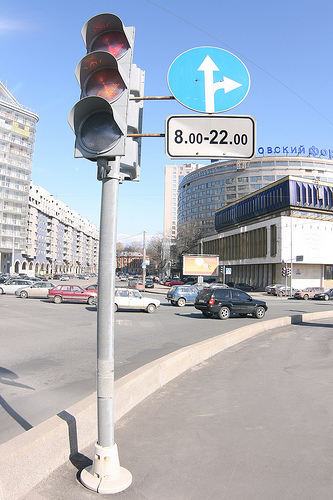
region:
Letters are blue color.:
[258, 142, 332, 158]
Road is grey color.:
[195, 405, 300, 466]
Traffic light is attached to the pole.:
[76, 16, 138, 186]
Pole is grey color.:
[100, 306, 119, 425]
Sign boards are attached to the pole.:
[163, 50, 257, 161]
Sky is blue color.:
[221, 14, 320, 46]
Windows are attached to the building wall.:
[3, 181, 68, 253]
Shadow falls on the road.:
[2, 367, 88, 469]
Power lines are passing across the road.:
[165, 8, 237, 49]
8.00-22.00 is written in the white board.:
[171, 119, 253, 158]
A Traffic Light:
[61, 9, 146, 166]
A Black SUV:
[190, 282, 269, 318]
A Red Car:
[43, 279, 95, 305]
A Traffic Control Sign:
[162, 41, 253, 112]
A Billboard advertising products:
[174, 246, 220, 278]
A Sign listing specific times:
[161, 112, 254, 156]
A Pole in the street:
[78, 179, 135, 484]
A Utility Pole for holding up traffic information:
[136, 226, 151, 285]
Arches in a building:
[11, 257, 91, 275]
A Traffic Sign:
[292, 252, 310, 267]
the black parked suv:
[193, 287, 261, 333]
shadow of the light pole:
[4, 362, 87, 467]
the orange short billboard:
[183, 249, 224, 288]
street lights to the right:
[278, 259, 297, 283]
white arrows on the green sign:
[183, 50, 252, 122]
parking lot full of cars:
[11, 273, 260, 327]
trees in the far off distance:
[122, 232, 167, 276]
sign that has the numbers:
[151, 113, 303, 177]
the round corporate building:
[171, 177, 316, 238]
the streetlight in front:
[76, 33, 140, 454]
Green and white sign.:
[166, 40, 255, 124]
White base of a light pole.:
[56, 408, 160, 496]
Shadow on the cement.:
[0, 357, 89, 492]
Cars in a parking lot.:
[0, 276, 274, 325]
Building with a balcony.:
[3, 186, 53, 263]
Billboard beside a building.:
[159, 241, 233, 286]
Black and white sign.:
[136, 116, 285, 187]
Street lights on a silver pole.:
[25, 26, 155, 486]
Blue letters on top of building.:
[248, 131, 328, 191]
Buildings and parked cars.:
[10, 137, 321, 305]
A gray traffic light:
[65, 12, 142, 184]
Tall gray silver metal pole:
[97, 179, 120, 447]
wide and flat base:
[78, 441, 134, 493]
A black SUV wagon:
[193, 286, 267, 320]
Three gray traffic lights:
[281, 266, 293, 276]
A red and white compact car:
[47, 283, 97, 305]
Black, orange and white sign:
[180, 252, 220, 277]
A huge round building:
[175, 156, 331, 277]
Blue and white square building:
[196, 175, 331, 298]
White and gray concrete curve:
[0, 309, 331, 498]